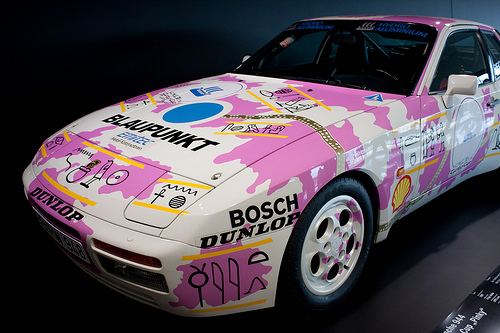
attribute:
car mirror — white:
[442, 73, 481, 108]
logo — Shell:
[384, 170, 426, 214]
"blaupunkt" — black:
[100, 111, 224, 166]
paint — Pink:
[232, 95, 366, 202]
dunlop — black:
[200, 217, 315, 249]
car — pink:
[86, 18, 487, 294]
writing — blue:
[373, 18, 428, 39]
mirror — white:
[415, 73, 499, 105]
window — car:
[443, 33, 485, 90]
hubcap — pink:
[302, 193, 363, 294]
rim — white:
[13, 4, 473, 331]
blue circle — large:
[154, 93, 234, 128]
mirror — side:
[438, 70, 498, 100]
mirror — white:
[439, 76, 494, 121]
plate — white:
[18, 202, 118, 276]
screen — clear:
[312, 29, 404, 93]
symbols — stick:
[31, 92, 283, 227]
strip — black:
[423, 282, 480, 327]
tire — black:
[284, 173, 392, 295]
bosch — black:
[230, 193, 299, 228]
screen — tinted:
[239, 16, 438, 97]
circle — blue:
[160, 97, 226, 124]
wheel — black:
[279, 171, 376, 311]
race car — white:
[31, 18, 494, 320]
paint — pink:
[253, 143, 313, 171]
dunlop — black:
[24, 185, 87, 228]